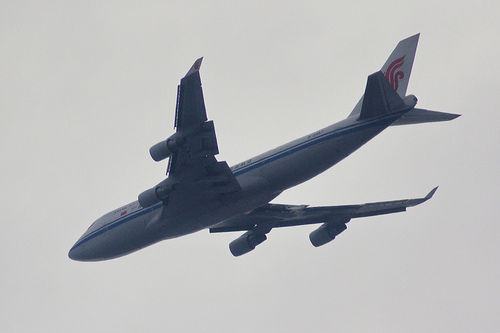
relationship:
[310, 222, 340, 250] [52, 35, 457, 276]
turbine of plane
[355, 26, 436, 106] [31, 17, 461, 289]
wing of plane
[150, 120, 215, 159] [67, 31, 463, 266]
turbine of plane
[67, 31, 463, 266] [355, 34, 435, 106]
plane has wing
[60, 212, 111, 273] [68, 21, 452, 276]
front of plane